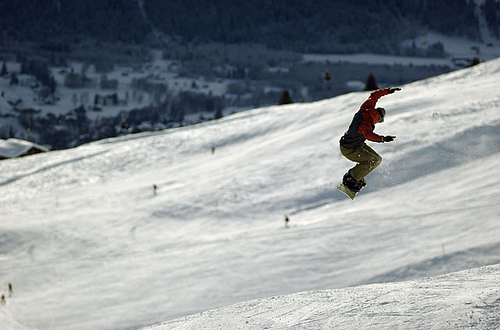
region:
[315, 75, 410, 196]
this is a person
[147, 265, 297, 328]
this is a white ice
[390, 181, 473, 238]
this is a white ice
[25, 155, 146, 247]
this is a white ice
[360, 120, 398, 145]
this is a person's hand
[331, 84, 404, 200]
a snowboarder performing a stunt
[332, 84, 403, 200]
a man jumping into the air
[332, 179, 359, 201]
a white snow board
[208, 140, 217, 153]
a black pole in the snow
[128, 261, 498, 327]
a nearby snow covered slope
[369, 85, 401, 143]
two outstretched man's arms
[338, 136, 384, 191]
snow pants on a man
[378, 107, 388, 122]
a hat on a man's head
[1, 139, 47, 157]
the snow covered roof of a house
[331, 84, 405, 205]
Person on a snowboard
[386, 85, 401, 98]
person wearing black gloves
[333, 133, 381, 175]
man wearing brown pants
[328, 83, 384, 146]
man wearing a red jacket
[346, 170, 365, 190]
man wearing black shoes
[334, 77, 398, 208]
person in the air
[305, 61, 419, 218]
skateboarder on the snow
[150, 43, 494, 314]
skateboarder is on a hill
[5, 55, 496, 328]
a hill covered with snow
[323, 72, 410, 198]
skateboarder wearing red shirt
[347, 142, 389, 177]
the knees are bend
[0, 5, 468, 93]
trees in the mountain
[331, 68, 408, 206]
man has extended arms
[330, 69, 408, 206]
man is on the side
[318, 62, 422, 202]
skateboarder is wearing a hat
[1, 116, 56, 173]
roof of home covers with snow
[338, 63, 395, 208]
snowboarder or snowy hill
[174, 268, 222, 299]
white snow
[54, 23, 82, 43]
white clouds in blue sky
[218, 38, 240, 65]
white clouds in blue sky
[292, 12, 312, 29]
white clouds in blue sky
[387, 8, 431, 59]
white clouds in blue sky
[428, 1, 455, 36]
white clouds in blue sky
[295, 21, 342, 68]
white clouds in blue sky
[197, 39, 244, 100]
white clouds in blue sky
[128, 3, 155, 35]
white clouds in blue sky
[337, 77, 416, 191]
snowboarder jumping on the mountain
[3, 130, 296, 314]
flag markers in the snow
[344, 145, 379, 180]
pants the snowboarder is wearing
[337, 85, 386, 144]
jacket the snowboarder is wearing